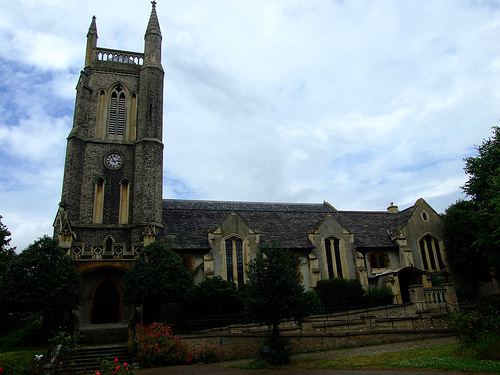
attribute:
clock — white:
[103, 152, 123, 171]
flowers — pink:
[124, 318, 204, 364]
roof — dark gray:
[160, 196, 416, 251]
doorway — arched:
[86, 273, 124, 325]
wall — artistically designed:
[65, 220, 147, 259]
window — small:
[410, 210, 434, 221]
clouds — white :
[1, 0, 485, 252]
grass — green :
[175, 336, 485, 374]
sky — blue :
[0, 59, 71, 131]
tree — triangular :
[124, 237, 193, 327]